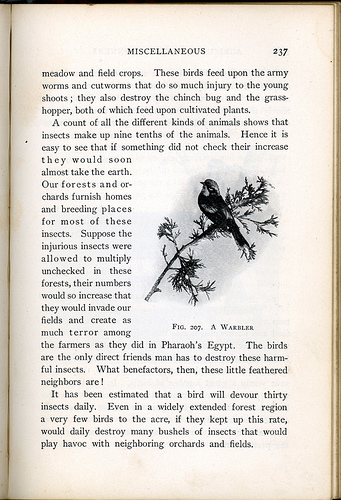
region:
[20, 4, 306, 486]
The page of a book.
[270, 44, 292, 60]
The number 237 at top book page.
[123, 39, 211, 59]
The word MISCELLANEOUS at top of book page.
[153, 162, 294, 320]
A black and white picture.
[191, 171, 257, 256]
Black and white picture of a bird.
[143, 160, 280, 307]
Bird sitting on tree limb.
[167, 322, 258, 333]
FIG. 207. A WARBLER written on book page.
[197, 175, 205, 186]
Beak of bird in a picture.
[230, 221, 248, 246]
Tail feathers of bird in a picture.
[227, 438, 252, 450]
Last word of page is fields.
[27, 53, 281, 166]
a passage referring to a bird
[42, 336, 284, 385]
speaks on the farmers and egypt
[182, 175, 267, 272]
this is a warbler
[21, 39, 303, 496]
a page from a book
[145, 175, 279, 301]
An image in shown in the book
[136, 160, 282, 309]
The image is of a bird on a branch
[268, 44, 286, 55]
The page number of the book is 237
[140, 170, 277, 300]
There are many leaves on this branch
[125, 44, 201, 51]
The title of this chapter is Miscellaneous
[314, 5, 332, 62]
A stain is shown on this page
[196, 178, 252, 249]
The bird is mostly colored in black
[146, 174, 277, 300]
The picture is colored in black and white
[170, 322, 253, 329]
The artist of the picture is named Warbler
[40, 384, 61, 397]
text in a book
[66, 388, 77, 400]
text in a book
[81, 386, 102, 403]
text in a book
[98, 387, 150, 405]
text in a book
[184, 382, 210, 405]
text in a book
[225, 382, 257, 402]
text in a book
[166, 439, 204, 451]
text in a book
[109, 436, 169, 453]
text in a book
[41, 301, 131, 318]
text in a book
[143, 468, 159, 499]
Page out of a book.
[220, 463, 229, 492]
Page out of a book.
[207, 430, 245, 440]
Page out of a book.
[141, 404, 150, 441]
Page out of a book.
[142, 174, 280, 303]
drawing of a bird on a branch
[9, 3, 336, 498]
page of a printed book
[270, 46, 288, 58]
printed page number 237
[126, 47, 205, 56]
printed chapter name miscellaneous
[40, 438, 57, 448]
black printed word play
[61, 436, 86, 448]
black printed word havoc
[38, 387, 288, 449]
a printed paragraph of text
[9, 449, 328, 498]
bottom margin of page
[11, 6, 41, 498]
inside printed page gutter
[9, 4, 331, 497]
light tan page of a book with black letters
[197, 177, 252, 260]
black and white illustration of a bird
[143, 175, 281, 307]
black and white illustration of a small tree branch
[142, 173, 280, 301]
black and white illustration of a bird sitting on a branch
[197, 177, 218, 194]
black and white illustration of a bird head and beak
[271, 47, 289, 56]
black numbers indicating the book page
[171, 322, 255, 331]
black letters indicating information about the illustration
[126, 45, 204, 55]
Title of the chapter of a book written in black letters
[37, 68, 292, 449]
black words written in book form